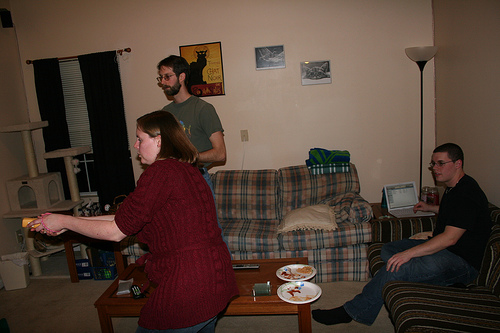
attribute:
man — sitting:
[362, 138, 492, 288]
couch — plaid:
[365, 198, 498, 330]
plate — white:
[272, 255, 326, 310]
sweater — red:
[115, 156, 243, 323]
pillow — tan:
[276, 202, 339, 242]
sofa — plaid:
[216, 159, 371, 267]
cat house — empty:
[3, 120, 82, 217]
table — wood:
[91, 252, 316, 332]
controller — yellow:
[20, 214, 45, 231]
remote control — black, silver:
[231, 259, 262, 273]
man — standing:
[153, 49, 220, 137]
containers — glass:
[423, 189, 439, 204]